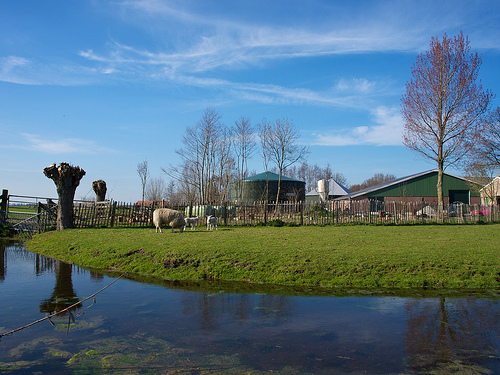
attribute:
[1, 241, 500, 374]
water — murky, clear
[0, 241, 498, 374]
pond — murky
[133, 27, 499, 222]
trees — bare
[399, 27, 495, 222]
tree — bare, tall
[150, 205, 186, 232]
animal — brown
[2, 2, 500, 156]
clouds — white, wispy, large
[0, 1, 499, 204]
sky — blue, cloudy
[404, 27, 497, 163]
leaves — red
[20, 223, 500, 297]
grass — low cut, green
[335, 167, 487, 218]
building — green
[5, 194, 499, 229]
fence — wooden, wood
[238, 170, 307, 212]
silo — green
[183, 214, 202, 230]
lamb — white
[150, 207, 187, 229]
sheep — furry, white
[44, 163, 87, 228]
tree — cut-off, branchless, leafless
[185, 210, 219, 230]
baby animals — twins, white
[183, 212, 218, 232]
lambs — white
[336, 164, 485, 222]
house — green, brown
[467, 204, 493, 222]
car — pink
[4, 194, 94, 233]
gate — metal